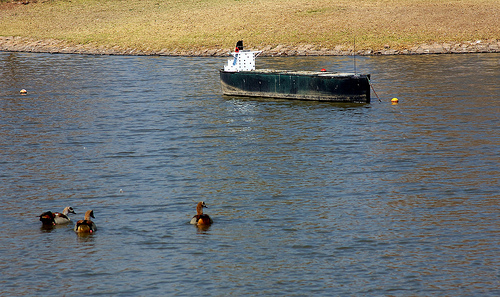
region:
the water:
[288, 171, 349, 288]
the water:
[311, 233, 357, 293]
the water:
[291, 239, 321, 295]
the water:
[333, 222, 354, 275]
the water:
[320, 242, 338, 289]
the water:
[303, 235, 326, 281]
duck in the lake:
[157, 183, 237, 235]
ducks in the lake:
[37, 185, 130, 240]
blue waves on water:
[249, 175, 369, 252]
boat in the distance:
[201, 44, 383, 111]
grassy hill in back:
[57, 5, 484, 51]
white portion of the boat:
[215, 35, 273, 67]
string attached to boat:
[365, 72, 397, 109]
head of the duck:
[192, 195, 214, 210]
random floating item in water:
[8, 75, 43, 107]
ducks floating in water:
[28, 154, 272, 256]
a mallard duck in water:
[182, 195, 219, 225]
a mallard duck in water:
[69, 207, 100, 233]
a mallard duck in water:
[37, 199, 75, 226]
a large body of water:
[3, 49, 498, 286]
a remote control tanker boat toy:
[210, 38, 374, 107]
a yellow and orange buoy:
[385, 90, 400, 105]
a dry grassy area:
[3, 2, 496, 47]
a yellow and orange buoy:
[14, 83, 28, 91]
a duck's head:
[193, 199, 210, 213]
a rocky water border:
[4, 28, 498, 59]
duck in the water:
[181, 175, 233, 255]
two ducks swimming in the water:
[21, 191, 125, 273]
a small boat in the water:
[190, 31, 407, 127]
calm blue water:
[273, 170, 418, 257]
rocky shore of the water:
[66, 30, 171, 70]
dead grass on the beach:
[132, 12, 192, 44]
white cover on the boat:
[214, 30, 272, 80]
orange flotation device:
[368, 87, 415, 129]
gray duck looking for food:
[32, 193, 77, 238]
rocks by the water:
[415, 30, 480, 57]